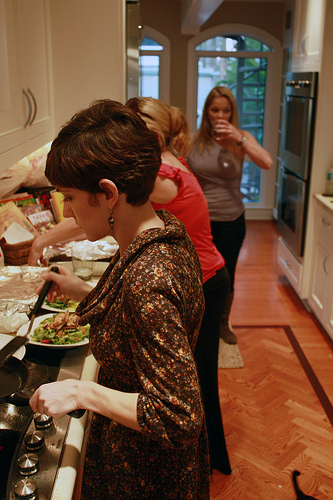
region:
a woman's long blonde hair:
[188, 84, 240, 156]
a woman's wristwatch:
[235, 131, 248, 144]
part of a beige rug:
[216, 320, 247, 373]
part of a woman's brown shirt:
[75, 209, 208, 499]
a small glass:
[68, 243, 96, 278]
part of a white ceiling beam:
[176, 0, 218, 35]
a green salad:
[33, 317, 87, 346]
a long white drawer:
[272, 240, 305, 286]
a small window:
[194, 36, 273, 55]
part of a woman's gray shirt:
[180, 130, 244, 219]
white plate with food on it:
[20, 298, 111, 361]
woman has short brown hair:
[46, 104, 200, 225]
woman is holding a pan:
[24, 340, 194, 458]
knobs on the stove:
[20, 411, 54, 498]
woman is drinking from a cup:
[192, 81, 265, 222]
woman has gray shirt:
[183, 124, 259, 237]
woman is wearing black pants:
[206, 213, 267, 339]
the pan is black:
[1, 341, 79, 441]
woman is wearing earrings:
[91, 205, 140, 234]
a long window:
[195, 54, 271, 207]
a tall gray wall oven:
[270, 68, 317, 259]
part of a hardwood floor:
[229, 219, 304, 325]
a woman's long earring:
[105, 208, 116, 234]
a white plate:
[15, 312, 89, 349]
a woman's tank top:
[151, 153, 229, 286]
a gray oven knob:
[16, 453, 41, 473]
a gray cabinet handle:
[20, 89, 33, 131]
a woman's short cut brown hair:
[42, 95, 162, 212]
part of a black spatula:
[0, 265, 60, 362]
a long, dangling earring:
[105, 206, 118, 231]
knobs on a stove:
[15, 414, 53, 498]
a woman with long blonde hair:
[196, 82, 243, 157]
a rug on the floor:
[219, 322, 242, 370]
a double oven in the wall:
[277, 70, 318, 262]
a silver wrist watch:
[237, 132, 248, 147]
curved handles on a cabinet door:
[22, 86, 38, 128]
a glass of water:
[70, 244, 95, 281]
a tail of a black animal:
[289, 466, 318, 498]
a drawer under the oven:
[274, 238, 302, 293]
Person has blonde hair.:
[200, 80, 246, 119]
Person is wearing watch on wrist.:
[234, 129, 251, 156]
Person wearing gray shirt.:
[207, 150, 231, 183]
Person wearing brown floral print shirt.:
[157, 380, 177, 426]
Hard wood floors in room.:
[243, 413, 286, 483]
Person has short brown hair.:
[80, 128, 119, 165]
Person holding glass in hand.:
[205, 113, 238, 148]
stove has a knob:
[32, 412, 52, 430]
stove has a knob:
[25, 430, 43, 448]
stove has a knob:
[17, 451, 38, 473]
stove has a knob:
[14, 477, 38, 496]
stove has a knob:
[305, 77, 309, 84]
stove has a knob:
[300, 78, 305, 84]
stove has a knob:
[297, 79, 301, 85]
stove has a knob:
[289, 80, 294, 84]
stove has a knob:
[286, 79, 289, 84]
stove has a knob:
[287, 78, 292, 86]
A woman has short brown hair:
[39, 91, 165, 246]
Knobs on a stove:
[4, 396, 59, 494]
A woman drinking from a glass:
[183, 74, 278, 179]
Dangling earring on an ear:
[89, 165, 126, 234]